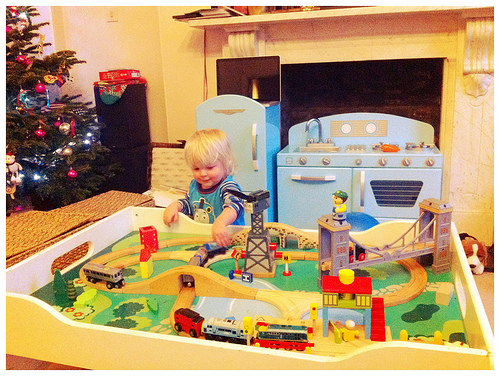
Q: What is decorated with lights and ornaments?
A: Christmas tree.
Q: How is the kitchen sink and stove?
A: Toy.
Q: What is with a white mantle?
A: Fireplace.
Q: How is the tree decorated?
A: With christmas decorations.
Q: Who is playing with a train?
A: Little boy in blue.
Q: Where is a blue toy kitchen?
A: Behind little boy.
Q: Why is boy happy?
A: Toys and christmas.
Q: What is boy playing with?
A: Toy train.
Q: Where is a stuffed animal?
A: Floor behind boy on right.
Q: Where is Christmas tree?
A: Near little boy.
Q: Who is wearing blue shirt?
A: Little blonde boy.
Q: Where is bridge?
A: Toy train playground.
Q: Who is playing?
A: A small child.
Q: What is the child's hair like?
A: Blonde.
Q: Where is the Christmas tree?
A: In the corner.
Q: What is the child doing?
A: Playing.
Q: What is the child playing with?
A: A toy train.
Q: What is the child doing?
A: Playing.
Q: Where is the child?
A: Next to the toys.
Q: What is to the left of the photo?
A: A christmas tree.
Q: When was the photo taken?
A: During the day.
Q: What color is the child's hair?
A: Blonde.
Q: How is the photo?
A: Clear.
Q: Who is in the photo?
A: A child.